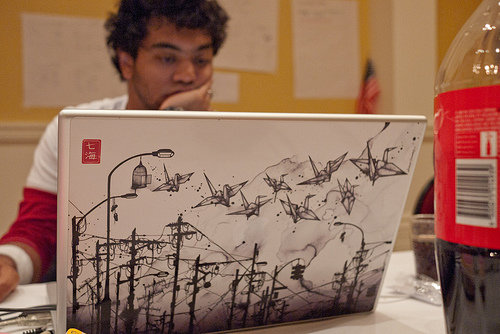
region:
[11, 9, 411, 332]
The man is on his laptop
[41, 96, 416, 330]
The back of the laptop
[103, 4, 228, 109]
The head of the man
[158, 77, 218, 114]
The hand of the man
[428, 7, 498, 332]
The coke bottle on the table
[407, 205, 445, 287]
A glass of soda on the table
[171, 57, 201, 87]
The nose of the man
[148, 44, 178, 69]
The eye of the man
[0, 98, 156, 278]
The man has on a red and white shirt on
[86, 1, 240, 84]
The man has black hair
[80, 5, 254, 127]
man in a relaxed tired position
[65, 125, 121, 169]
Asian sign on silver back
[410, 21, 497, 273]
coke drink in a bottle with upc showing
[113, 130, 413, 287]
graphic design drawing on laptop back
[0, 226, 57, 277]
sweat rag on the wrist of a man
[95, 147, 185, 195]
graphic design birdcage and lamp post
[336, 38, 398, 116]
american flag and yellow wall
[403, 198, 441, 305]
dark drink next to plastic baggie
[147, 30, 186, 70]
Large eyebrows and big man eye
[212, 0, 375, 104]
posters on a yellow board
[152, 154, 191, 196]
The bird is black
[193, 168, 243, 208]
The bird is black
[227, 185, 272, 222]
The bird is black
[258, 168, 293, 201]
The bird is black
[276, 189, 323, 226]
The bird is black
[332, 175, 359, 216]
The bird is black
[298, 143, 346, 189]
The bird is black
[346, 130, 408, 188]
The bird is black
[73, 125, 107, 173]
The symbol is red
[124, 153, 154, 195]
The bird cage is black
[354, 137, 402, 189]
Small dowing on the face of a laptop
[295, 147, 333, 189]
Small dowing on the face of a laptop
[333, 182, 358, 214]
Small dowing on the face of a laptop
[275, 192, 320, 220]
Small dowing on the face of a laptop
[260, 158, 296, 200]
Small dowing on the face of a laptop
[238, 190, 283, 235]
Small dowing on the face of a laptop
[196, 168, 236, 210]
Small dowing on the face of a laptop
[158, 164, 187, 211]
Small dowing on the face of a laptop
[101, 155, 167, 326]
Small dowing on the face of a laptop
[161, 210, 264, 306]
Small dowing on the face of a laptop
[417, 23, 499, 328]
a 2 liter of soda is in front of the man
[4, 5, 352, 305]
a man can be seen behind the laptop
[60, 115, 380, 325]
the outside of the laptop has a design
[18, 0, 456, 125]
paper hangs behind the man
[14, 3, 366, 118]
paper is hung up on the wall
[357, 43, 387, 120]
a flag is behind the man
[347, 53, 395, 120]
an American Flag is in the corner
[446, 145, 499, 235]
the bottles bar code is visible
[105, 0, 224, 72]
the man has dark curly hair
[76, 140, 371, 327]
street lamps are part of the design